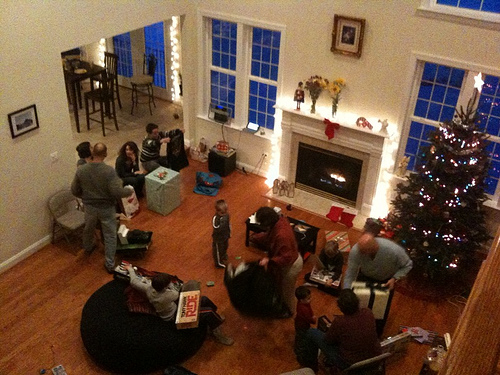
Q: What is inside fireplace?
A: A fire.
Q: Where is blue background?
A: Outside windows.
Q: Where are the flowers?
A: The mantle.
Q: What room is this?
A: Living Room.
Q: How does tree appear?
A: Decorated.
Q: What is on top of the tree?
A: A star.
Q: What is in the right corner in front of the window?
A: A Christmas tree.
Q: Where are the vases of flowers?
A: On the mantle.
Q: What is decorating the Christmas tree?
A: Lights.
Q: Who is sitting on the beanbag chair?
A: A child.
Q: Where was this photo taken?
A: Inside someone's house.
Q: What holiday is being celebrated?
A: Christmas.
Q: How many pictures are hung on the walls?
A: Two.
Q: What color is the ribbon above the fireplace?
A: Red.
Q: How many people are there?
A: Eleven.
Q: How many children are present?
A: Three.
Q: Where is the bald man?
A: In front of the Christmas tree.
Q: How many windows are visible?
A: Five.